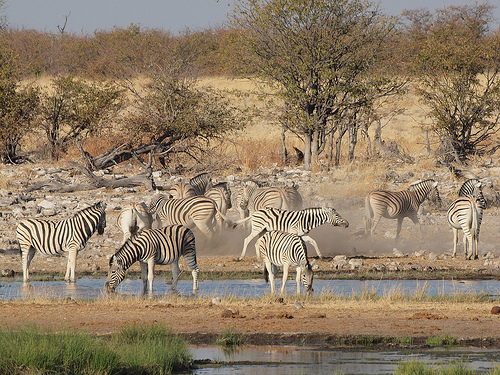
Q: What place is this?
A: It is a field.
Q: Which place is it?
A: It is a field.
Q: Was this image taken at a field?
A: Yes, it was taken in a field.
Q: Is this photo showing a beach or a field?
A: It is showing a field.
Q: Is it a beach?
A: No, it is a field.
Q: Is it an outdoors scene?
A: Yes, it is outdoors.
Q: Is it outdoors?
A: Yes, it is outdoors.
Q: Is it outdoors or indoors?
A: It is outdoors.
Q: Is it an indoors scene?
A: No, it is outdoors.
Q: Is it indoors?
A: No, it is outdoors.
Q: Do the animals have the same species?
A: Yes, all the animals are zebras.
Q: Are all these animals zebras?
A: Yes, all the animals are zebras.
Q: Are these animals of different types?
A: No, all the animals are zebras.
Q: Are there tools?
A: No, there are no tools.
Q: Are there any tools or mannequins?
A: No, there are no tools or mannequins.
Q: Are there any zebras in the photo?
A: Yes, there is a zebra.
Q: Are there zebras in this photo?
A: Yes, there is a zebra.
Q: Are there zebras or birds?
A: Yes, there is a zebra.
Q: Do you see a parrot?
A: No, there are no parrots.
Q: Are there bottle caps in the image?
A: No, there are no bottle caps.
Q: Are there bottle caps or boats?
A: No, there are no bottle caps or boats.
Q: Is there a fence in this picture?
A: No, there are no fences.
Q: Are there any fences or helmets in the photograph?
A: No, there are no fences or helmets.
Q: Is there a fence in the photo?
A: No, there are no fences.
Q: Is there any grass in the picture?
A: Yes, there is grass.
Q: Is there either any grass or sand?
A: Yes, there is grass.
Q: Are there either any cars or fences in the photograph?
A: No, there are no fences or cars.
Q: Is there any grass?
A: Yes, there is grass.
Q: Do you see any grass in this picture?
A: Yes, there is grass.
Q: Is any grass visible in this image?
A: Yes, there is grass.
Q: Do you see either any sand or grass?
A: Yes, there is grass.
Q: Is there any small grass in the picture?
A: Yes, there is small grass.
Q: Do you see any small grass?
A: Yes, there is small grass.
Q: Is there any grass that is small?
A: Yes, there is grass that is small.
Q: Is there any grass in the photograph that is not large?
A: Yes, there is small grass.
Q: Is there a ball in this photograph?
A: No, there are no balls.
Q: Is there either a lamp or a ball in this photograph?
A: No, there are no balls or lamps.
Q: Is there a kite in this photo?
A: No, there are no kites.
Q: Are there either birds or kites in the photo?
A: No, there are no kites or birds.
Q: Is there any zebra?
A: Yes, there is a zebra.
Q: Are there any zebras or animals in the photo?
A: Yes, there is a zebra.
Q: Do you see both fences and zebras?
A: No, there is a zebra but no fences.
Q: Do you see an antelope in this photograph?
A: No, there are no antelopes.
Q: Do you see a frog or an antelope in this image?
A: No, there are no antelopes or frogs.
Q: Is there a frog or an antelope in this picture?
A: No, there are no antelopes or frogs.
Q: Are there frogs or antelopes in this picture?
A: No, there are no antelopes or frogs.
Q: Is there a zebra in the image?
A: Yes, there is a zebra.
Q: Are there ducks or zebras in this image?
A: Yes, there is a zebra.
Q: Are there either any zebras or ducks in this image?
A: Yes, there is a zebra.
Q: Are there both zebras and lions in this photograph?
A: No, there is a zebra but no lions.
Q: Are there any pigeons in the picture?
A: No, there are no pigeons.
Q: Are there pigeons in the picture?
A: No, there are no pigeons.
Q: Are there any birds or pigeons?
A: No, there are no pigeons or birds.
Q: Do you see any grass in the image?
A: Yes, there is grass.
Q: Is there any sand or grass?
A: Yes, there is grass.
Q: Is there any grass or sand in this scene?
A: Yes, there is grass.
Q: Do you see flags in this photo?
A: No, there are no flags.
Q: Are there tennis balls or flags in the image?
A: No, there are no flags or tennis balls.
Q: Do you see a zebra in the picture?
A: Yes, there is a zebra.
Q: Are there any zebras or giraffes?
A: Yes, there is a zebra.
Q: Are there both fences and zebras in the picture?
A: No, there is a zebra but no fences.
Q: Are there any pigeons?
A: No, there are no pigeons.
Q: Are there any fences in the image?
A: No, there are no fences.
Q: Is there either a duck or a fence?
A: No, there are no fences or ducks.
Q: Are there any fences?
A: No, there are no fences.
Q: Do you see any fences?
A: No, there are no fences.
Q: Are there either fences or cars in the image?
A: No, there are no fences or cars.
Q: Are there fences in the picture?
A: No, there are no fences.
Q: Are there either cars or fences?
A: No, there are no fences or cars.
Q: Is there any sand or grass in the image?
A: Yes, there is grass.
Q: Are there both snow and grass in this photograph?
A: No, there is grass but no snow.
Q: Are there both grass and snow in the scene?
A: No, there is grass but no snow.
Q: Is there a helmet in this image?
A: No, there are no helmets.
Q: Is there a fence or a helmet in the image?
A: No, there are no helmets or fences.